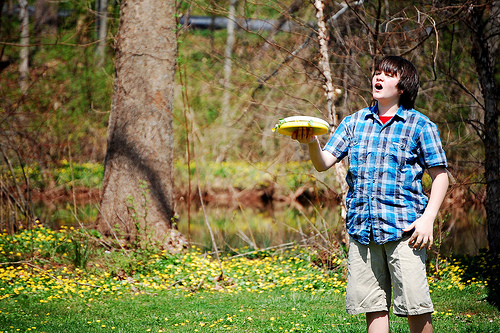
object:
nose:
[374, 71, 384, 84]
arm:
[303, 121, 349, 173]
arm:
[413, 118, 452, 227]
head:
[370, 55, 418, 102]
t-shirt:
[376, 116, 392, 125]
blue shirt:
[319, 104, 448, 247]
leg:
[343, 236, 390, 332]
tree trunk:
[309, 0, 355, 257]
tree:
[90, 0, 182, 250]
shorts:
[343, 236, 433, 320]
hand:
[401, 218, 435, 251]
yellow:
[40, 235, 51, 242]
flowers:
[63, 237, 74, 244]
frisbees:
[271, 114, 331, 139]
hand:
[290, 126, 319, 150]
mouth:
[371, 82, 384, 93]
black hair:
[369, 54, 421, 111]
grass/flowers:
[0, 246, 499, 332]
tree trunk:
[90, 0, 180, 244]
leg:
[382, 237, 435, 332]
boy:
[290, 55, 450, 332]